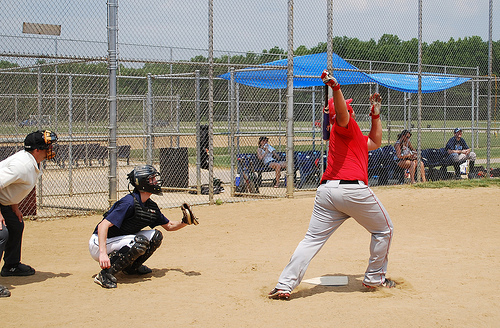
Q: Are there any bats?
A: Yes, there is a bat.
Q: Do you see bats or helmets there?
A: Yes, there is a bat.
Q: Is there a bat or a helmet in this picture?
A: Yes, there is a bat.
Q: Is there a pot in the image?
A: No, there are no pots.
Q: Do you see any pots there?
A: No, there are no pots.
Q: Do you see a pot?
A: No, there are no pots.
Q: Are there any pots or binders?
A: No, there are no pots or binders.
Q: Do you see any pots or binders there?
A: No, there are no pots or binders.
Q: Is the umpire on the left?
A: Yes, the umpire is on the left of the image.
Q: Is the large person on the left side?
A: Yes, the umpire is on the left of the image.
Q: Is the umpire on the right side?
A: No, the umpire is on the left of the image.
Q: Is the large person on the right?
A: No, the umpire is on the left of the image.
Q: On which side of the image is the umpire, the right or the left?
A: The umpire is on the left of the image.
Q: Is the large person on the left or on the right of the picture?
A: The umpire is on the left of the image.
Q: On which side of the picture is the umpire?
A: The umpire is on the left of the image.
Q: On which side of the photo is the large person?
A: The umpire is on the left of the image.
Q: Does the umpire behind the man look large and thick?
A: Yes, the umpire is large and thick.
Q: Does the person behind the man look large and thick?
A: Yes, the umpire is large and thick.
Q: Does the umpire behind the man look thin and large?
A: No, the umpire is large but thick.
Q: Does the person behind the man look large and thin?
A: No, the umpire is large but thick.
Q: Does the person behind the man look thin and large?
A: No, the umpire is large but thick.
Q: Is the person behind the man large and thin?
A: No, the umpire is large but thick.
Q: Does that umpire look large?
A: Yes, the umpire is large.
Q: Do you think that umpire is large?
A: Yes, the umpire is large.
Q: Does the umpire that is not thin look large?
A: Yes, the umpire is large.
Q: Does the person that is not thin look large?
A: Yes, the umpire is large.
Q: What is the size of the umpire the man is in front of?
A: The umpire is large.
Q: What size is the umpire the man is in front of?
A: The umpire is large.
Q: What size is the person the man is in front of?
A: The umpire is large.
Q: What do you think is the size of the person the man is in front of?
A: The umpire is large.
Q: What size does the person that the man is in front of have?
A: The umpire has large size.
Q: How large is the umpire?
A: The umpire is large.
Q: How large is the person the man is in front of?
A: The umpire is large.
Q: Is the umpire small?
A: No, the umpire is large.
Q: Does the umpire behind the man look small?
A: No, the umpire is large.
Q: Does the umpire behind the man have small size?
A: No, the umpire is large.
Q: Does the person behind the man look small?
A: No, the umpire is large.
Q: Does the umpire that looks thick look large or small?
A: The umpire is large.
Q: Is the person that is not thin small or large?
A: The umpire is large.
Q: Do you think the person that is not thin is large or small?
A: The umpire is large.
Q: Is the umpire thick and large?
A: Yes, the umpire is thick and large.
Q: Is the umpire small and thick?
A: No, the umpire is thick but large.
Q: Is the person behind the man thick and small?
A: No, the umpire is thick but large.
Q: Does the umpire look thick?
A: Yes, the umpire is thick.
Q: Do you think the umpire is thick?
A: Yes, the umpire is thick.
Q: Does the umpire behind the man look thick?
A: Yes, the umpire is thick.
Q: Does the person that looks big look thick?
A: Yes, the umpire is thick.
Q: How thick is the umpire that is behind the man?
A: The umpire is thick.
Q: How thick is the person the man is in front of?
A: The umpire is thick.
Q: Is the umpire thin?
A: No, the umpire is thick.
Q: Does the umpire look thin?
A: No, the umpire is thick.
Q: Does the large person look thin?
A: No, the umpire is thick.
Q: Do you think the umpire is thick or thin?
A: The umpire is thick.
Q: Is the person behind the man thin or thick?
A: The umpire is thick.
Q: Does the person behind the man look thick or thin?
A: The umpire is thick.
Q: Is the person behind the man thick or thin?
A: The umpire is thick.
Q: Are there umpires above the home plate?
A: Yes, there is an umpire above the home plate.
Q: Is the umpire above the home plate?
A: Yes, the umpire is above the home plate.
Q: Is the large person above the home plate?
A: Yes, the umpire is above the home plate.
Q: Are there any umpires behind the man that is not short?
A: Yes, there is an umpire behind the man.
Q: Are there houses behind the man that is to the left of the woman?
A: No, there is an umpire behind the man.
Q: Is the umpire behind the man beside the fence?
A: Yes, the umpire is behind the man.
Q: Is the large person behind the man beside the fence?
A: Yes, the umpire is behind the man.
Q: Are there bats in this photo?
A: Yes, there is a bat.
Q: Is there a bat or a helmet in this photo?
A: Yes, there is a bat.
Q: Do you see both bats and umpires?
A: Yes, there are both a bat and an umpire.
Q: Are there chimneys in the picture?
A: No, there are no chimneys.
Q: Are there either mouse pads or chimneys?
A: No, there are no chimneys or mouse pads.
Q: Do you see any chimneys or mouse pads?
A: No, there are no chimneys or mouse pads.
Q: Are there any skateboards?
A: No, there are no skateboards.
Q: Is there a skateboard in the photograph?
A: No, there are no skateboards.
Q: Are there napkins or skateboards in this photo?
A: No, there are no skateboards or napkins.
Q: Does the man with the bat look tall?
A: Yes, the man is tall.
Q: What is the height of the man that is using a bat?
A: The man is tall.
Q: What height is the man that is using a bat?
A: The man is tall.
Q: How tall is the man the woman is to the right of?
A: The man is tall.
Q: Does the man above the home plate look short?
A: No, the man is tall.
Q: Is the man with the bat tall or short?
A: The man is tall.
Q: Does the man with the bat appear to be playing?
A: Yes, the man is playing.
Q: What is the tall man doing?
A: The man is playing.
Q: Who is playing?
A: The man is playing.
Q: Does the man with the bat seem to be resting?
A: No, the man is playing.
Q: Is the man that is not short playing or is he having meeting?
A: The man is playing.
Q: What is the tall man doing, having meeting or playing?
A: The man is playing.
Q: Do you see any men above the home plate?
A: Yes, there is a man above the home plate.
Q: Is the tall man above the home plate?
A: Yes, the man is above the home plate.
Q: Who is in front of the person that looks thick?
A: The man is in front of the umpire.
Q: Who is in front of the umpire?
A: The man is in front of the umpire.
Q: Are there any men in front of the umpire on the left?
A: Yes, there is a man in front of the umpire.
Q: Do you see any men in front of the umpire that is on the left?
A: Yes, there is a man in front of the umpire.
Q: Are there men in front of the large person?
A: Yes, there is a man in front of the umpire.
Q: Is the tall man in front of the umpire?
A: Yes, the man is in front of the umpire.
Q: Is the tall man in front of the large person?
A: Yes, the man is in front of the umpire.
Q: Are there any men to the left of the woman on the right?
A: Yes, there is a man to the left of the woman.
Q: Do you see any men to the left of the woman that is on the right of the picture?
A: Yes, there is a man to the left of the woman.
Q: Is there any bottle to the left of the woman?
A: No, there is a man to the left of the woman.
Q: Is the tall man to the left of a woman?
A: Yes, the man is to the left of a woman.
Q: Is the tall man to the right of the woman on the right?
A: No, the man is to the left of the woman.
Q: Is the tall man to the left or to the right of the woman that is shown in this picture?
A: The man is to the left of the woman.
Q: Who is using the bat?
A: The man is using the bat.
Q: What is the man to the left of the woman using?
A: The man is using a bat.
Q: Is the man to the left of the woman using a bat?
A: Yes, the man is using a bat.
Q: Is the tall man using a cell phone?
A: No, the man is using a bat.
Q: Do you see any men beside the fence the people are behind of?
A: Yes, there is a man beside the fence.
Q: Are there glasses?
A: No, there are no glasses.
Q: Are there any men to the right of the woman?
A: Yes, there is a man to the right of the woman.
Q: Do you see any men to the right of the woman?
A: Yes, there is a man to the right of the woman.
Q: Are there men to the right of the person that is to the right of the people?
A: Yes, there is a man to the right of the woman.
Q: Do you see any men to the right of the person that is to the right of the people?
A: Yes, there is a man to the right of the woman.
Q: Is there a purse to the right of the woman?
A: No, there is a man to the right of the woman.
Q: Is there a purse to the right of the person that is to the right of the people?
A: No, there is a man to the right of the woman.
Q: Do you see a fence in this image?
A: Yes, there is a fence.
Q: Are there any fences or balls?
A: Yes, there is a fence.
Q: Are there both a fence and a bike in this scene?
A: No, there is a fence but no bikes.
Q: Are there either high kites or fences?
A: Yes, there is a high fence.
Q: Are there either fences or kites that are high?
A: Yes, the fence is high.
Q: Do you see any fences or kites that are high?
A: Yes, the fence is high.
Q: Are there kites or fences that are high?
A: Yes, the fence is high.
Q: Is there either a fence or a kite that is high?
A: Yes, the fence is high.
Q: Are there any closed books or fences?
A: Yes, there is a closed fence.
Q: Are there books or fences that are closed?
A: Yes, the fence is closed.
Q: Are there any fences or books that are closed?
A: Yes, the fence is closed.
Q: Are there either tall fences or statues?
A: Yes, there is a tall fence.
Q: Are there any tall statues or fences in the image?
A: Yes, there is a tall fence.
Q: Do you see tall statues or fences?
A: Yes, there is a tall fence.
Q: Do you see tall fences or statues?
A: Yes, there is a tall fence.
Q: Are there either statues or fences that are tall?
A: Yes, the fence is tall.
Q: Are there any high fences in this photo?
A: Yes, there is a high fence.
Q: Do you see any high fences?
A: Yes, there is a high fence.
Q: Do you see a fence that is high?
A: Yes, there is a fence that is high.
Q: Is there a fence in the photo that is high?
A: Yes, there is a fence that is high.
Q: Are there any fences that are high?
A: Yes, there is a fence that is high.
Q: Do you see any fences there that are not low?
A: Yes, there is a high fence.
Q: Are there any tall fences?
A: Yes, there is a tall fence.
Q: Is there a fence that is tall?
A: Yes, there is a fence that is tall.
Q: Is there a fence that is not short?
A: Yes, there is a tall fence.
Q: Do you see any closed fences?
A: Yes, there is a closed fence.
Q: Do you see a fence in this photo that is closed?
A: Yes, there is a fence that is closed.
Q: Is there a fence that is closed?
A: Yes, there is a fence that is closed.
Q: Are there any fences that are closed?
A: Yes, there is a fence that is closed.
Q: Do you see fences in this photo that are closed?
A: Yes, there is a fence that is closed.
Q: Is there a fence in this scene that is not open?
A: Yes, there is an closed fence.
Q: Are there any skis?
A: No, there are no skis.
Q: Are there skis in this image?
A: No, there are no skis.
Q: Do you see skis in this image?
A: No, there are no skis.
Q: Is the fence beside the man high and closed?
A: Yes, the fence is high and closed.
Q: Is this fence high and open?
A: No, the fence is high but closed.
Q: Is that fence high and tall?
A: Yes, the fence is high and tall.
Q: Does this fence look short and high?
A: No, the fence is high but tall.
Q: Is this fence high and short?
A: No, the fence is high but tall.